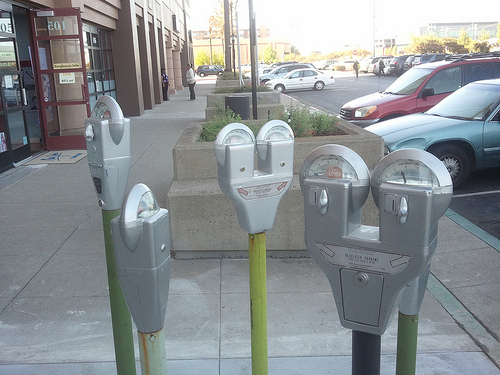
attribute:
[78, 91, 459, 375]
parking meters — grouped, gathered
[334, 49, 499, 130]
van — red, parked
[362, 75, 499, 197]
car — blue, parked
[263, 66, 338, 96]
car — white, parked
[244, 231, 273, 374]
pole — light green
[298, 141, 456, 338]
meter — silver, double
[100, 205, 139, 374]
pole — dark green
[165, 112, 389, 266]
planter — concrete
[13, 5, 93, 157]
door — open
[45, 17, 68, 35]
number — 105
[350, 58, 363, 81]
man — standing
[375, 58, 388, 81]
person — walking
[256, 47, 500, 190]
cars — parked